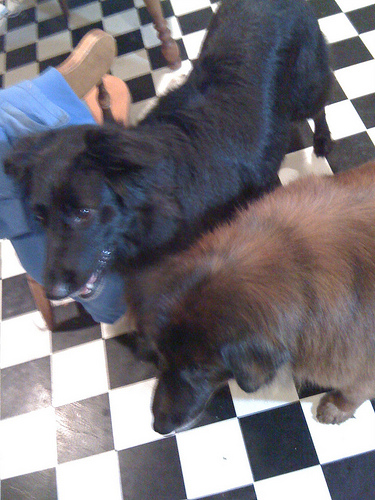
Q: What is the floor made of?
A: Tile.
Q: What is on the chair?
A: A shirt.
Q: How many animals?
A: Two.